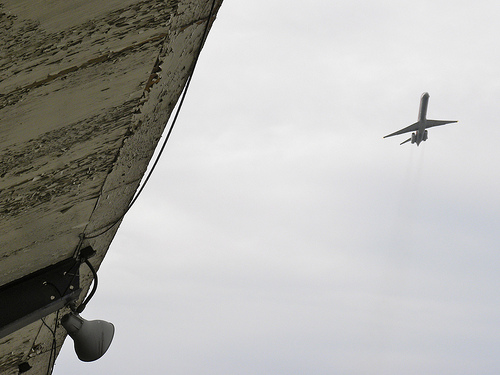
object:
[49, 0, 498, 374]
sky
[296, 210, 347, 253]
clouds